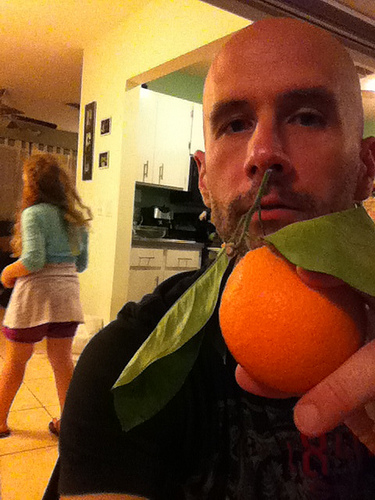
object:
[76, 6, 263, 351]
wall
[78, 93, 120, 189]
pictures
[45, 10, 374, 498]
man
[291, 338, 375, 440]
finger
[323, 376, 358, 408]
ridges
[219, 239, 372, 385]
orange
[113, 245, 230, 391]
leaf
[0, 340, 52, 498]
floor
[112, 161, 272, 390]
stem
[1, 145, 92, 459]
woman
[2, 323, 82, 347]
shorts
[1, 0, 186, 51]
ceiling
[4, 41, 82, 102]
shadow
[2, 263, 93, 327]
shirt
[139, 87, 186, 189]
cabinet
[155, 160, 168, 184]
handle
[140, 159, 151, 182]
handle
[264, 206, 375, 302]
leaves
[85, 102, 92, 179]
frames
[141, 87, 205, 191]
cabinet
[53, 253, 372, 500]
shirt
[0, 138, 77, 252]
curtain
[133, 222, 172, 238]
bowl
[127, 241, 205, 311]
counter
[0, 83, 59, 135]
ceiling fan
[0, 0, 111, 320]
room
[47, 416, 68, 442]
sandals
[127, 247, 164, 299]
cabinet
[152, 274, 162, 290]
silvertone handle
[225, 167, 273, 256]
branches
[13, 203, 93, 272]
sweater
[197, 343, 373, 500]
pattern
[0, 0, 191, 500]
background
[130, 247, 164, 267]
drawer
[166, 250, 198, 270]
drawer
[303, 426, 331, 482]
'8'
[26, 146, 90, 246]
hair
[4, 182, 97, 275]
cascading curls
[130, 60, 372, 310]
kitchen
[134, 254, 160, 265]
handle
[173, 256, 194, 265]
handle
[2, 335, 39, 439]
leg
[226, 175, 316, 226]
shave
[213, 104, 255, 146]
eyes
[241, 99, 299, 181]
nose